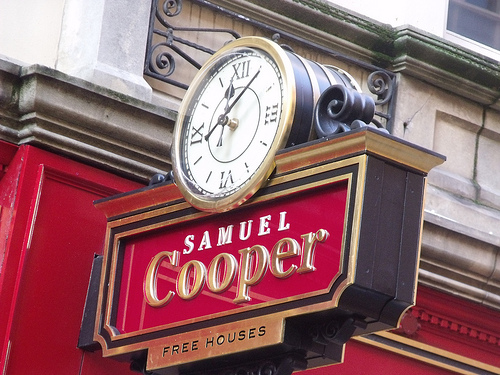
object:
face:
[178, 47, 283, 198]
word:
[143, 229, 327, 307]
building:
[0, 0, 499, 374]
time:
[203, 60, 261, 147]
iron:
[145, 0, 398, 128]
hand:
[203, 69, 261, 141]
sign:
[147, 317, 282, 370]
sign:
[115, 178, 348, 336]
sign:
[90, 36, 445, 374]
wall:
[0, 0, 499, 374]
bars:
[153, 28, 215, 55]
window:
[447, 0, 500, 50]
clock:
[170, 36, 296, 214]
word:
[182, 211, 291, 255]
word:
[205, 325, 266, 348]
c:
[143, 250, 178, 307]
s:
[181, 234, 194, 255]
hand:
[215, 73, 237, 147]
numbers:
[240, 59, 251, 79]